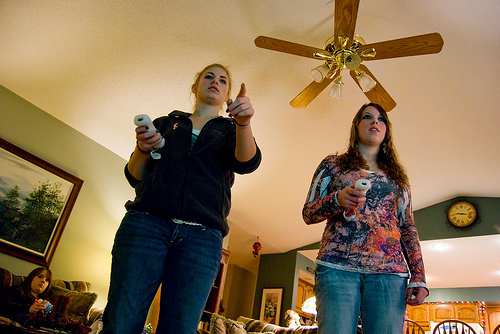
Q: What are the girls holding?
A: Wii controls.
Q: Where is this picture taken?
A: The living room.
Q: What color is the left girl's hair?
A: Blonde.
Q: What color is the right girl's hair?
A: Brown.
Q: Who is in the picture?
A: Two girls.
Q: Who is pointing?
A: The girl on the left.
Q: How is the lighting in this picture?
A: Dim.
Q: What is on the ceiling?
A: A fan.